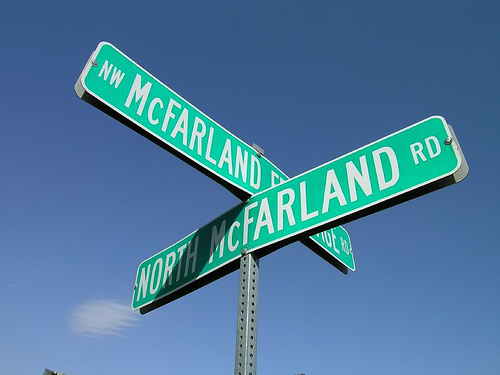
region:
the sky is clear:
[29, 134, 92, 232]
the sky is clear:
[36, 158, 118, 211]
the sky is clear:
[374, 258, 433, 368]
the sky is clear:
[224, 32, 316, 107]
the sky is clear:
[393, 213, 448, 311]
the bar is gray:
[234, 248, 284, 373]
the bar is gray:
[232, 253, 252, 368]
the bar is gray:
[217, 249, 265, 370]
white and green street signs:
[75, 53, 470, 307]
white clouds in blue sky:
[298, 282, 323, 300]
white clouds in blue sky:
[388, 291, 429, 318]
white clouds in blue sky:
[288, 301, 325, 339]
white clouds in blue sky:
[37, 289, 89, 329]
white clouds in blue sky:
[88, 306, 150, 370]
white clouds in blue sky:
[341, 65, 365, 90]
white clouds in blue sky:
[255, 61, 316, 148]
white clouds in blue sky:
[22, 115, 69, 173]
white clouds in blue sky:
[87, 209, 137, 247]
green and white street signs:
[55, 52, 449, 282]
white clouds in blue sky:
[315, 298, 370, 345]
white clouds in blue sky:
[31, 295, 73, 326]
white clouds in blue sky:
[407, 295, 468, 337]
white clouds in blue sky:
[301, 298, 349, 350]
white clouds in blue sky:
[412, 279, 493, 329]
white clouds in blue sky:
[48, 298, 133, 359]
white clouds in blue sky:
[31, 171, 57, 211]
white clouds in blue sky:
[278, 46, 326, 97]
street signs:
[68, 39, 469, 313]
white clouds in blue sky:
[50, 301, 104, 335]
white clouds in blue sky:
[348, 282, 406, 337]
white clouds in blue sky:
[278, 292, 305, 320]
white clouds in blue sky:
[384, 295, 429, 343]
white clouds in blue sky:
[391, 208, 443, 260]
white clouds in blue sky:
[297, 59, 357, 109]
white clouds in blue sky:
[372, 12, 427, 73]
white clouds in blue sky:
[225, 29, 262, 84]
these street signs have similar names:
[66, 29, 470, 319]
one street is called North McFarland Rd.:
[128, 113, 474, 315]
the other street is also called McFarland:
[68, 35, 266, 197]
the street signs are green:
[66, 34, 475, 322]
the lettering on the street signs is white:
[64, 33, 474, 319]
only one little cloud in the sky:
[6, 6, 222, 363]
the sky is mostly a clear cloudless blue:
[4, 3, 494, 124]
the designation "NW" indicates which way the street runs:
[90, 49, 137, 100]